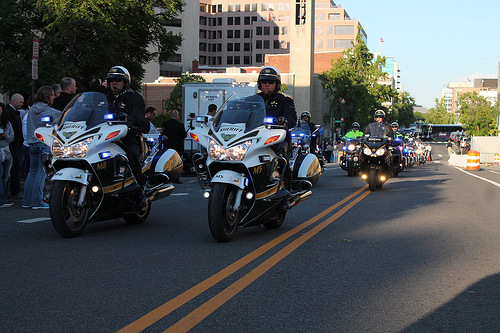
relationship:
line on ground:
[115, 183, 374, 333] [6, 142, 492, 331]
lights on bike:
[190, 130, 280, 158] [186, 111, 379, 245]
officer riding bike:
[239, 65, 298, 210] [32, 90, 184, 237]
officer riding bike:
[93, 65, 148, 208] [185, 84, 322, 243]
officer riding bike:
[364, 109, 395, 151] [350, 134, 401, 192]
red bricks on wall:
[311, 49, 345, 75] [268, 50, 345, 77]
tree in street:
[5, 1, 182, 103] [22, 134, 488, 325]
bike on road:
[186, 92, 322, 242] [0, 158, 493, 331]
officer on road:
[239, 65, 298, 210] [0, 158, 493, 331]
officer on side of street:
[364, 109, 395, 151] [6, 143, 487, 331]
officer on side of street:
[300, 111, 323, 169] [6, 143, 487, 331]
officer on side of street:
[239, 65, 298, 210] [6, 143, 487, 331]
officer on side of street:
[93, 65, 148, 208] [6, 143, 487, 331]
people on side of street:
[50, 70, 85, 117] [6, 143, 487, 331]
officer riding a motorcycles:
[239, 65, 298, 210] [191, 66, 321, 241]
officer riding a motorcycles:
[93, 65, 148, 208] [35, 65, 183, 237]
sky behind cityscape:
[335, 3, 497, 78] [2, 83, 495, 328]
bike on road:
[34, 91, 184, 238] [0, 158, 493, 331]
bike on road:
[351, 122, 401, 191] [0, 158, 493, 331]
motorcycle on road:
[309, 129, 338, 167] [0, 158, 493, 331]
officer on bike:
[229, 65, 294, 220] [186, 92, 322, 242]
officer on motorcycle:
[367, 105, 391, 149] [26, 84, 168, 234]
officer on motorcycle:
[91, 63, 149, 203] [355, 133, 399, 193]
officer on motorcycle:
[364, 109, 395, 151] [351, 130, 396, 195]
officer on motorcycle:
[93, 65, 148, 208] [204, 90, 308, 249]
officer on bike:
[93, 65, 148, 208] [34, 91, 184, 238]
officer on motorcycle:
[386, 119, 402, 150] [397, 130, 414, 170]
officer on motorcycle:
[294, 103, 319, 143] [139, 116, 194, 197]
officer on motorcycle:
[364, 109, 395, 151] [356, 121, 398, 192]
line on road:
[157, 183, 375, 331] [0, 158, 493, 331]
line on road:
[115, 183, 374, 333] [0, 158, 493, 331]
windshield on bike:
[55, 90, 110, 130] [32, 90, 184, 237]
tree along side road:
[453, 92, 497, 139] [0, 158, 493, 331]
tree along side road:
[422, 96, 463, 125] [0, 158, 493, 331]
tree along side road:
[325, 23, 397, 124] [0, 158, 493, 331]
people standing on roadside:
[6, 58, 86, 197] [0, 156, 490, 331]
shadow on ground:
[382, 269, 485, 331] [103, 204, 498, 331]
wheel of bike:
[205, 182, 246, 242] [186, 92, 322, 242]